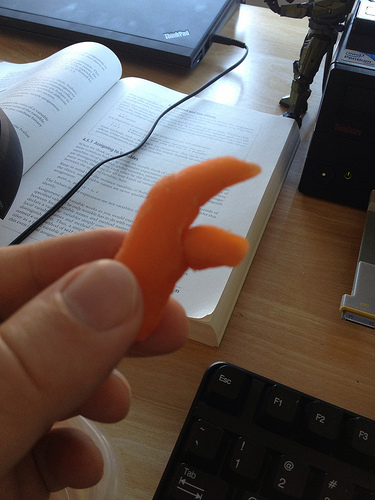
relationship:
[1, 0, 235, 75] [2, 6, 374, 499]
laptop on desk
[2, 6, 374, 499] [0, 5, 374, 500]
desk made of wood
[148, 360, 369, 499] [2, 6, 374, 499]
keyboard on desk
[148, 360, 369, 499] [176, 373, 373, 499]
keyboard has lettering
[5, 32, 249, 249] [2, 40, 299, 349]
wire over book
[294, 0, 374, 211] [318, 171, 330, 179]
computer has light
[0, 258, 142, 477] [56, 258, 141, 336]
finger has nail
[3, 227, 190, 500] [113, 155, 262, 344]
hand holding carrot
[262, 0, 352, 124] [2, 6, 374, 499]
figurine standing on desk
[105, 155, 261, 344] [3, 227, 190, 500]
carrot in fingers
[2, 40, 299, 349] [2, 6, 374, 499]
book on desk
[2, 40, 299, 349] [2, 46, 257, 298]
book has words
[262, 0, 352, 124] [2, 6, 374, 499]
figurine on desk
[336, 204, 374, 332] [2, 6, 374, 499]
plug on desk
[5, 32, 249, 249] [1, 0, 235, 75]
wire plugged into laptop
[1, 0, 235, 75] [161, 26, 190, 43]
laptop has name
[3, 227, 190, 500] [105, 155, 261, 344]
hand holding food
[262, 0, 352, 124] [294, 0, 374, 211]
figurine leaning on computer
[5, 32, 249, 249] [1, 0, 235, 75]
wire attached to laptop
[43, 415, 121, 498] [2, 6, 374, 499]
plastic bag on desk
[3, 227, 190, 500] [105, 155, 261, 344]
fingers are holding carrot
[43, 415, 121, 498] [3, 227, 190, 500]
plastic bag under fingers